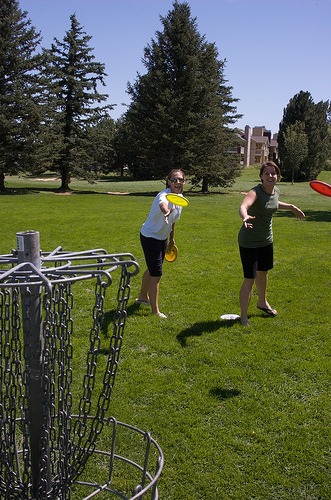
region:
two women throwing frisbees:
[132, 153, 315, 324]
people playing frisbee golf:
[104, 144, 314, 327]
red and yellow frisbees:
[160, 174, 330, 224]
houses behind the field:
[221, 119, 288, 170]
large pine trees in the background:
[9, 61, 250, 189]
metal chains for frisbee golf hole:
[7, 221, 159, 493]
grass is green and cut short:
[175, 357, 310, 481]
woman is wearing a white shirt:
[128, 165, 198, 246]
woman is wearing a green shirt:
[229, 177, 294, 281]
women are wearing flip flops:
[134, 283, 292, 329]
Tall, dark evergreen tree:
[110, 2, 244, 186]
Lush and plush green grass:
[142, 332, 316, 426]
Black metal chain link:
[2, 285, 118, 495]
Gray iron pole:
[13, 227, 52, 497]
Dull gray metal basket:
[107, 414, 167, 498]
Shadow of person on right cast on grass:
[163, 318, 238, 350]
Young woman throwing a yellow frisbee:
[164, 189, 190, 208]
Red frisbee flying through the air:
[304, 175, 329, 197]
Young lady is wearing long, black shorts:
[238, 240, 277, 278]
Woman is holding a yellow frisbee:
[165, 235, 179, 266]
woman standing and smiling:
[125, 161, 201, 321]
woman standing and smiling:
[237, 156, 296, 325]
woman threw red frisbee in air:
[230, 152, 328, 333]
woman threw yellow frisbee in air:
[136, 168, 191, 326]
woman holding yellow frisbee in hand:
[133, 162, 191, 327]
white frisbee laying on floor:
[206, 305, 242, 328]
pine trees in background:
[2, 33, 239, 193]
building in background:
[220, 119, 287, 173]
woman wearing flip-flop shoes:
[233, 279, 293, 343]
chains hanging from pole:
[0, 230, 136, 498]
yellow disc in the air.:
[166, 193, 191, 207]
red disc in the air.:
[312, 180, 330, 200]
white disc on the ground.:
[223, 312, 235, 320]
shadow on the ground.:
[211, 376, 244, 402]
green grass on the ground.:
[215, 449, 258, 479]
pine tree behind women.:
[196, 117, 225, 171]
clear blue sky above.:
[246, 20, 284, 49]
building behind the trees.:
[235, 135, 264, 162]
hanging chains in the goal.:
[75, 320, 122, 380]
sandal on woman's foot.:
[257, 304, 280, 316]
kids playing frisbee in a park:
[28, 145, 314, 318]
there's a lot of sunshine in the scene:
[35, 101, 304, 287]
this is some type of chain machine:
[10, 307, 182, 499]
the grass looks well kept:
[116, 283, 316, 484]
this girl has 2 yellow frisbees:
[140, 171, 205, 318]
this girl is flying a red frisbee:
[239, 157, 325, 327]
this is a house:
[218, 110, 287, 176]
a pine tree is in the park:
[15, 7, 109, 179]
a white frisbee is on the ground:
[208, 278, 290, 351]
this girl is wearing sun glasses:
[129, 152, 224, 234]